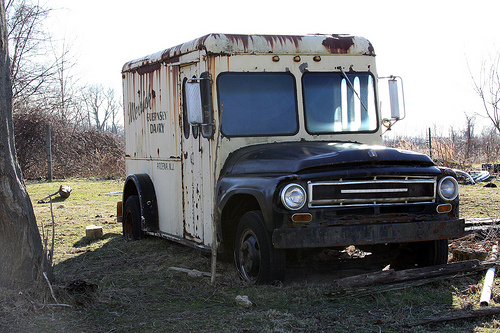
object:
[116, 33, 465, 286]
truck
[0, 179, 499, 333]
grass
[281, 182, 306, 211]
light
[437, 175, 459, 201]
light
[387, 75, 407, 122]
mirror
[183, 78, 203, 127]
mirror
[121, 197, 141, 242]
wheel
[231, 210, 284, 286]
wheel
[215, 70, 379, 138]
windshield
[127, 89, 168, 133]
writing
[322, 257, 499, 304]
log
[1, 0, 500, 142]
sky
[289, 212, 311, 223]
turnsignal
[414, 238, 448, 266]
wheel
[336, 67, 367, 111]
wiper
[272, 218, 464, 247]
bumper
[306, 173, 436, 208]
grill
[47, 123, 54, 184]
pole